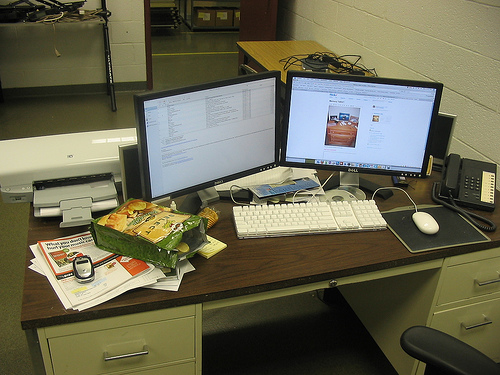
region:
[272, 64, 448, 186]
computer monitor with text displayed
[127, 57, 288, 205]
computer monitor with text displayed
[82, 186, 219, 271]
plastic bag filled with food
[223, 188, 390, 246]
computer keyboard with white keys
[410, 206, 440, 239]
plastic computer mouse colored white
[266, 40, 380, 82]
pile of black wires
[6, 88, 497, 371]
this is a desk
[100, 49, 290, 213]
this is a computer monitor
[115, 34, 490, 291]
two monitors on desk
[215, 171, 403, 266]
this is a keyboard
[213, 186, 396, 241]
the keyboard is white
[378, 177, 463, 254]
this is a mouse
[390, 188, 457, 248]
the mouse is white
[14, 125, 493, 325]
wooden top of desk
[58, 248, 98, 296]
this is a phone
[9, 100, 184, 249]
this is a printer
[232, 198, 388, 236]
white corded computer keyboard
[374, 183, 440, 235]
white corded computer mouse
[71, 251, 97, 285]
black and silver flip cellphone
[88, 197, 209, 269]
open bag of potato chips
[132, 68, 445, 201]
two black frame computer screens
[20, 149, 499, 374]
metal desk with brown top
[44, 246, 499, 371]
two sets of filing cabinets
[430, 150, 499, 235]
Black corded telephone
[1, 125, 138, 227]
shiny gray printer with paper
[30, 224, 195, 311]
cellphone on top of pile of paper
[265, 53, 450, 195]
computer monitor on desk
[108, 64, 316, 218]
computer monitor on desk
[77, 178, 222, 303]
pack of crackers on desk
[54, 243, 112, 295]
cell phone on desk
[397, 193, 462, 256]
white mouse on mouse pad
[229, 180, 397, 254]
white keyboard on desk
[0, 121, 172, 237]
printer on desk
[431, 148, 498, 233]
black phone on desk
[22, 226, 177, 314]
papers on desk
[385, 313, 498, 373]
black handle of chair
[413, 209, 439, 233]
white corded mouse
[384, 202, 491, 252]
black mouse pad under the mouse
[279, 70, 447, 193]
computer monitor next to computer monitor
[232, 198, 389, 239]
white keyboard in front of computer monitor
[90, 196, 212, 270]
green bag on top of the desk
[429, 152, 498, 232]
black phone on top of the desk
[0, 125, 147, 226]
printer behind computer monitor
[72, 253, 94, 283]
silver flip phone on top of a pile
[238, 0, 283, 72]
door is open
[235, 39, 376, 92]
table is visible behind computer monitor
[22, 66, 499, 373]
desk with two computer monitors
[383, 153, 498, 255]
phone next to mouse pad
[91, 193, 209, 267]
bag of chips next to monitor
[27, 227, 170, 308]
cell phone on top of papers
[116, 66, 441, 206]
Two computer monitors.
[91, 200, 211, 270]
An open bag of cookies.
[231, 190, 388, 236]
A white keyboard.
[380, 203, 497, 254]
A mouse sitting on a mousepad.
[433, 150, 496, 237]
A black office telephone.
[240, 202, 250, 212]
white key on the computer keyboard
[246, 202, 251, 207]
white key on the computer keyboard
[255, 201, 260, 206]
white key on the computer keyboard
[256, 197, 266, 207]
white key on the computer keyboard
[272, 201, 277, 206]
white key on the computer keyboard